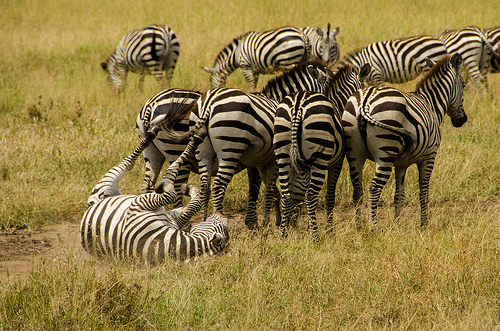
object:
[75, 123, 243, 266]
zebra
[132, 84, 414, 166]
four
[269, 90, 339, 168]
butts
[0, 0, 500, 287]
herd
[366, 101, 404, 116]
black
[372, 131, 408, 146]
stripes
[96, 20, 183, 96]
zebra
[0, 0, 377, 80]
background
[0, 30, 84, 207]
grass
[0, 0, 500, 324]
safari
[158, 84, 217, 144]
zebra's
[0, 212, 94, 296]
dirt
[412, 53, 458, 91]
mane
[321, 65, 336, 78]
perked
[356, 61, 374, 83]
ears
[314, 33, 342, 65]
face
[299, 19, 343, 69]
zebra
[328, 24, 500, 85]
two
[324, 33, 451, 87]
eating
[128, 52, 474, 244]
together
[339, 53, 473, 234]
zebra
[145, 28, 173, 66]
tail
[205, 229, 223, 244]
ears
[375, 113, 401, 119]
white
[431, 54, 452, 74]
brown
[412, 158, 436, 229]
legs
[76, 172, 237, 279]
down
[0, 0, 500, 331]
photo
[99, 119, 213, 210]
kicking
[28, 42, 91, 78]
green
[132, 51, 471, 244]
others